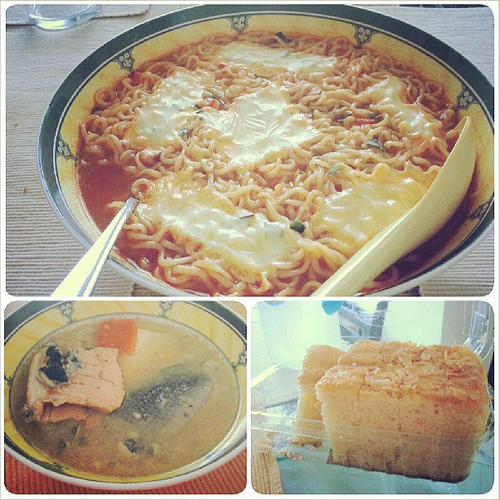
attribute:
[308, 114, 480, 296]
soup spoon — white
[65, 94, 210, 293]
spoon — silver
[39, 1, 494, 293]
bowl — yellow, green, black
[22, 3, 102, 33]
glass — for drinking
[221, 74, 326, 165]
cheese — melted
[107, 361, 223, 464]
fish — grey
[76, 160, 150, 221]
sauce — red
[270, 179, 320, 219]
noodles — white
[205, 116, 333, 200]
cheese — melted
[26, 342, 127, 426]
fish — white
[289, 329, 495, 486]
pastry — small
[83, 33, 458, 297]
noodles — white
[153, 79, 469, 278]
soup — noodle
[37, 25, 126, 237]
rim — green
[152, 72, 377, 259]
noodles — white